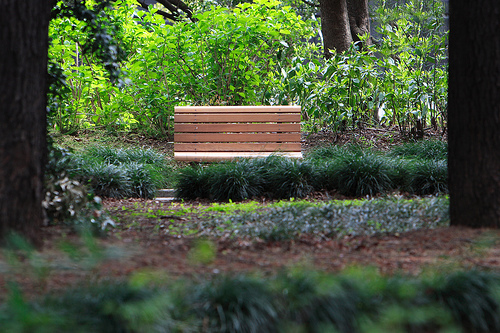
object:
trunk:
[2, 4, 49, 244]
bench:
[174, 106, 302, 161]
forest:
[7, 0, 500, 326]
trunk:
[445, 2, 499, 227]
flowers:
[387, 202, 429, 226]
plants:
[206, 1, 291, 103]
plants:
[177, 160, 245, 202]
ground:
[9, 141, 496, 279]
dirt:
[366, 235, 425, 270]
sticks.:
[326, 122, 450, 138]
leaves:
[96, 216, 118, 233]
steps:
[146, 194, 179, 202]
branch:
[155, 0, 213, 23]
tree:
[3, 2, 62, 238]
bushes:
[319, 147, 401, 199]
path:
[155, 185, 184, 206]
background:
[5, 0, 497, 126]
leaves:
[279, 238, 295, 254]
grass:
[240, 199, 441, 239]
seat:
[177, 135, 310, 163]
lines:
[20, 16, 31, 108]